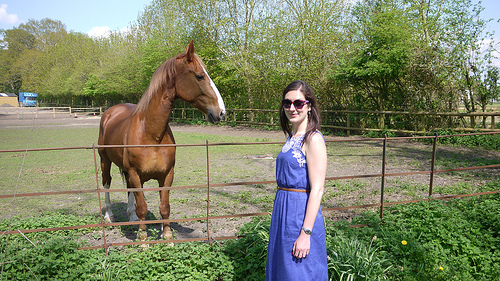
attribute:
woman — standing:
[264, 82, 330, 280]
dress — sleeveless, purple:
[267, 126, 331, 281]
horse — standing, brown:
[98, 41, 231, 251]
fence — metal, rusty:
[3, 126, 493, 259]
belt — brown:
[277, 184, 312, 195]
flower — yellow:
[401, 240, 409, 249]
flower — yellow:
[437, 264, 446, 272]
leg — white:
[99, 155, 118, 226]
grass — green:
[11, 130, 34, 141]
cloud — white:
[86, 26, 134, 44]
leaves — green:
[367, 60, 397, 76]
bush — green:
[332, 235, 394, 281]